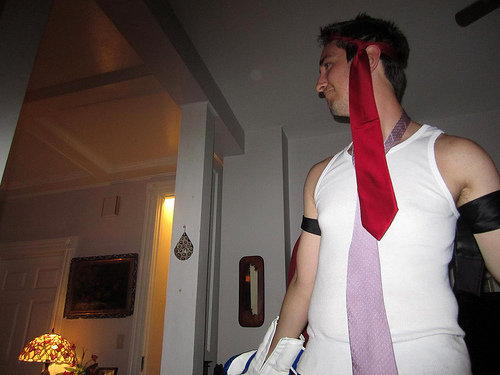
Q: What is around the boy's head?
A: A tie.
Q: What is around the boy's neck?
A: A tie.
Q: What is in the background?
A: A painting.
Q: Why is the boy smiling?
A: He is having fun.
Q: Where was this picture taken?
A: In a house.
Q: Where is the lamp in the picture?
A: Beside a door.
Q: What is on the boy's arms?
A: Arm bands.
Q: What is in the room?
A: A closed white door.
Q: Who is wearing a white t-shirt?
A: The man.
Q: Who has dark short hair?
A: The man.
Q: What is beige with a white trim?
A: The cantilevered ceiling.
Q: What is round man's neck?
A: Purple tie.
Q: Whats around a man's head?
A: Red tie.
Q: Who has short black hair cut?
A: A man.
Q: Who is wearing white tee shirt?
A: A man.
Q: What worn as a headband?
A: Red tie.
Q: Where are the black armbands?
A: Wrapped around the man's biceps.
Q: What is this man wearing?
A: White tank top shirt.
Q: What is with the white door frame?
A: White door.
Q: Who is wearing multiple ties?
A: The man.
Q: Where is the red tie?
A: Hanging from man's head.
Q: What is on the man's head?
A: A tie.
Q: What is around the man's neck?
A: A lavender tie.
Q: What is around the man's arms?
A: Black arm-bands.